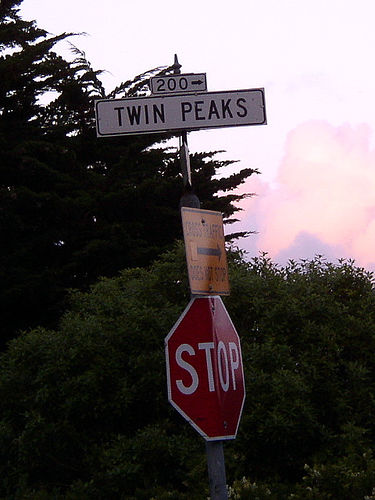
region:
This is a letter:
[106, 101, 125, 128]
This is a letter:
[124, 100, 143, 127]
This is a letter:
[143, 100, 152, 125]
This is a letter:
[149, 100, 167, 127]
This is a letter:
[178, 97, 194, 124]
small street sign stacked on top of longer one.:
[94, 72, 268, 137]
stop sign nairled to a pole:
[163, 294, 246, 498]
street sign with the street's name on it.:
[96, 86, 269, 137]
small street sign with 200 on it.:
[148, 72, 208, 95]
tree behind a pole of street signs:
[1, 1, 266, 343]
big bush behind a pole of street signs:
[3, 240, 374, 496]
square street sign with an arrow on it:
[180, 204, 230, 295]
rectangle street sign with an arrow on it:
[148, 72, 207, 93]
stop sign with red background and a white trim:
[161, 294, 246, 440]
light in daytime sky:
[3, 1, 373, 274]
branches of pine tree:
[0, 1, 262, 268]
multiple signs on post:
[93, 53, 268, 499]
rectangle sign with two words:
[94, 87, 268, 136]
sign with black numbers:
[150, 71, 205, 93]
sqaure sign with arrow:
[182, 207, 228, 294]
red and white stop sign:
[164, 294, 246, 442]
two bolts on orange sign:
[201, 218, 212, 289]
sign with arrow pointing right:
[150, 72, 206, 93]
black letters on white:
[114, 97, 247, 129]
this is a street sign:
[49, 53, 311, 470]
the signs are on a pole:
[114, 183, 342, 463]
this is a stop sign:
[188, 337, 302, 427]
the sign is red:
[146, 315, 270, 439]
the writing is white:
[131, 300, 318, 499]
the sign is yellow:
[152, 199, 265, 286]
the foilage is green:
[68, 272, 197, 428]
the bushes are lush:
[54, 292, 179, 431]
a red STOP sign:
[158, 293, 253, 441]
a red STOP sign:
[162, 300, 252, 444]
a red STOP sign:
[156, 296, 259, 444]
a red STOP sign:
[145, 295, 244, 451]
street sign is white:
[81, 91, 267, 143]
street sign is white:
[88, 89, 269, 144]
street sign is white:
[90, 94, 269, 134]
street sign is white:
[87, 90, 272, 140]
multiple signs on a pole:
[93, 49, 314, 498]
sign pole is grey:
[189, 413, 241, 498]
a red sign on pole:
[155, 257, 274, 458]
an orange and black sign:
[173, 200, 237, 301]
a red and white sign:
[158, 293, 259, 455]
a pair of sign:
[157, 182, 266, 446]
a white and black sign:
[79, 84, 275, 144]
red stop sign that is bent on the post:
[150, 291, 266, 449]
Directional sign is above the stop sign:
[158, 192, 249, 305]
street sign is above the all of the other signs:
[79, 57, 284, 150]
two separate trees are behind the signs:
[0, 6, 365, 412]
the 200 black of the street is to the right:
[130, 64, 214, 100]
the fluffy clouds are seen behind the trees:
[219, 96, 369, 291]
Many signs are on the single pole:
[75, 38, 270, 488]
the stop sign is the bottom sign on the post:
[155, 288, 269, 451]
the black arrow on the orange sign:
[182, 240, 232, 263]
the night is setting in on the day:
[8, 44, 369, 499]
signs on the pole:
[100, 19, 312, 189]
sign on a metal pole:
[175, 316, 248, 463]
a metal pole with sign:
[166, 269, 256, 455]